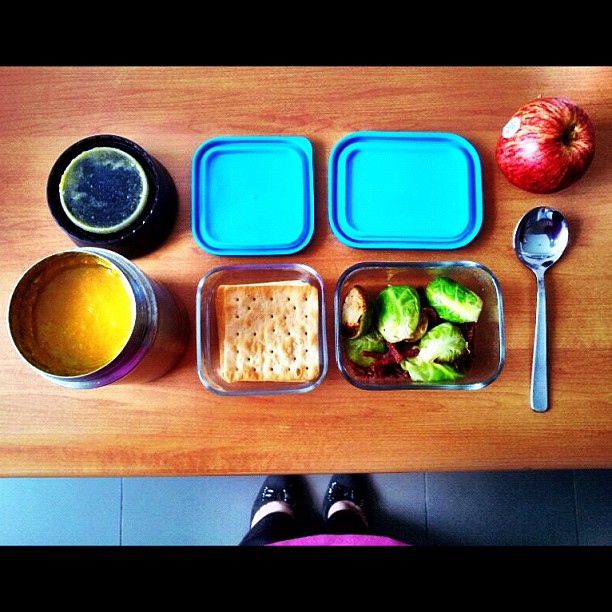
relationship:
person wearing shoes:
[238, 473, 414, 546] [254, 475, 365, 506]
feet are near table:
[242, 474, 376, 520] [13, 80, 604, 451]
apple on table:
[487, 86, 597, 200] [13, 80, 604, 451]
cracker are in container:
[216, 280, 320, 383] [195, 262, 328, 397]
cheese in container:
[51, 291, 97, 336] [3, 244, 188, 390]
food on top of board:
[10, 96, 591, 405] [9, 86, 609, 448]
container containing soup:
[3, 244, 188, 390] [21, 255, 133, 374]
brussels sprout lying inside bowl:
[338, 279, 371, 341] [333, 258, 505, 392]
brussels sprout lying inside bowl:
[373, 282, 420, 343] [333, 258, 505, 392]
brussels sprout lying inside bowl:
[422, 273, 484, 324] [333, 258, 505, 392]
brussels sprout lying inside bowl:
[413, 322, 469, 360] [333, 258, 505, 392]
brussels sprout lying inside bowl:
[398, 357, 462, 383] [333, 258, 505, 392]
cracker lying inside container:
[216, 280, 320, 383] [191, 260, 331, 400]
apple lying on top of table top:
[496, 98, 595, 195] [0, 66, 611, 477]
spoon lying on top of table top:
[510, 203, 571, 412] [2, 65, 591, 477]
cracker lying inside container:
[216, 280, 320, 383] [195, 262, 328, 397]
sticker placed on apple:
[502, 116, 521, 139] [496, 98, 595, 195]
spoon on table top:
[513, 205, 569, 412] [0, 66, 611, 477]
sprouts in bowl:
[342, 276, 484, 383] [322, 258, 523, 400]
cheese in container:
[35, 266, 106, 370] [5, 247, 189, 390]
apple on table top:
[496, 98, 595, 195] [0, 66, 611, 477]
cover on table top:
[42, 131, 168, 251] [0, 66, 611, 477]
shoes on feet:
[254, 475, 365, 506] [244, 481, 374, 522]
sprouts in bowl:
[363, 287, 473, 373] [333, 258, 505, 392]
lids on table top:
[191, 134, 315, 258] [0, 66, 611, 477]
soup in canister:
[21, 250, 131, 376] [11, 254, 184, 401]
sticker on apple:
[502, 116, 521, 139] [496, 98, 595, 195]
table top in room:
[0, 66, 611, 477] [7, 8, 591, 605]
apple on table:
[496, 98, 595, 195] [12, 399, 468, 440]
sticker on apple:
[502, 116, 521, 139] [491, 96, 592, 173]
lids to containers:
[191, 122, 489, 248] [190, 260, 517, 397]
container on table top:
[195, 262, 328, 397] [0, 66, 611, 477]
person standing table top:
[238, 473, 414, 546] [0, 66, 611, 477]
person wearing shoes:
[227, 481, 441, 581] [245, 469, 375, 525]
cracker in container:
[216, 280, 320, 383] [185, 255, 335, 405]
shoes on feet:
[247, 472, 369, 526] [245, 478, 379, 539]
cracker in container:
[211, 277, 326, 387] [195, 262, 328, 397]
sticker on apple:
[499, 114, 527, 142] [487, 86, 597, 200]